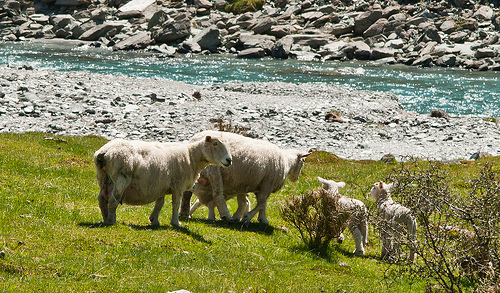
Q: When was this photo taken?
A: During the daytime.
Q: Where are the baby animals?
A: Behind the shrubs.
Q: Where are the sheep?
A: Walking in the grass.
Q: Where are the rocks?
A: Near the water.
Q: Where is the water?
A: Behind the sheep.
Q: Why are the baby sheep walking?
A: To keep up with the adult sheep.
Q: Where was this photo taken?
A: In a field by the water.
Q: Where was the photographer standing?
A: Behind the group of sheep.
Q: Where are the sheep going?
A: The river.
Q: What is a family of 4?
A: The sheep.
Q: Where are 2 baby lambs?
A: On right.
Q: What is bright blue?
A: Flowing water.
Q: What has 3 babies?
A: Sheep family.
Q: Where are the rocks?
A: In background.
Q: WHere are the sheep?
A: On grass.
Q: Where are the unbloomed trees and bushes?
A: Near babies.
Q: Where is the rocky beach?
A: Behind sheep.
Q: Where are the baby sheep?
A: In grass.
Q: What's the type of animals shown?
A: Lambs.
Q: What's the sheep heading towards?
A: Water.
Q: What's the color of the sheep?
A: White.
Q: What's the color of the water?
A: Blue.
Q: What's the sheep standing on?
A: Grass.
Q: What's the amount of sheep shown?
A: Four.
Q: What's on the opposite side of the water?
A: Rocks.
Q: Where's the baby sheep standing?
A: Near bush.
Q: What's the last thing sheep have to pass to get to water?
A: Rocks.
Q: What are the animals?
A: Sheep.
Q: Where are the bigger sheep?
A: On the left.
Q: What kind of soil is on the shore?
A: Rocky.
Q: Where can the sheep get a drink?
A: The creek.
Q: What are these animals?
A: Sheep.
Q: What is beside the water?
A: Rocks.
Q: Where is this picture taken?
A: In a field.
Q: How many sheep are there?
A: Four.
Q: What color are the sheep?
A: White.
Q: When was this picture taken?
A: During the daytime.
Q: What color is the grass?
A: Green.